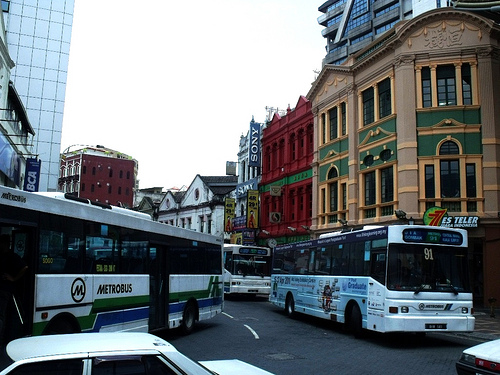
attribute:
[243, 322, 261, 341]
line — white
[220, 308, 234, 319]
line — white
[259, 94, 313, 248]
building — tall, red, old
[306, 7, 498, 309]
building — green, gold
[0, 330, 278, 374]
car — white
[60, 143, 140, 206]
building — red, brick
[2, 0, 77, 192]
building — glass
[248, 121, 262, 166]
sign — blue, white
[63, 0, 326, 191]
sky — cloudy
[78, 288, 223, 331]
stripes — blue, green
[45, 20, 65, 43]
window — glass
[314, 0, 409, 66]
building — tall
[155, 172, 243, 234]
building — white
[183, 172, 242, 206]
roof — pointed